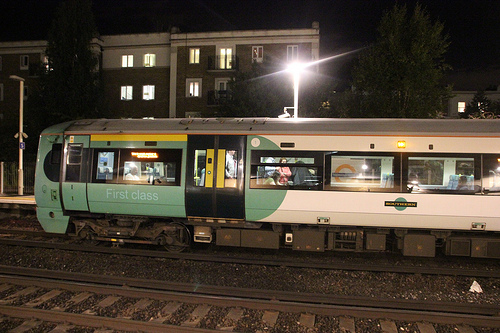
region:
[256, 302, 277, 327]
cross tie on the track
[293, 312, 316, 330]
cross tie on the track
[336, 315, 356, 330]
cross tie on the track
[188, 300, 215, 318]
cross tie on the track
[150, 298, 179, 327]
cross tie on the track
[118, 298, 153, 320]
cross tie on the track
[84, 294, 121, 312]
cross tie on the track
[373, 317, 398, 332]
cross tie on the track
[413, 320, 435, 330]
cross tie on the track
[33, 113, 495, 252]
the long train going down the track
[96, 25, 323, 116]
the building next to the trees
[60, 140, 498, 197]
the line of windows on the train compartment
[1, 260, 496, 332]
the empty track next to the train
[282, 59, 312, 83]
a very bright street light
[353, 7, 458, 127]
the many green leaves on the tree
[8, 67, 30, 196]
another street light that is not turned on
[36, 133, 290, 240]
the green section of the paint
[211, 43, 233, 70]
the double doors next to the balcony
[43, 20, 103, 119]
another leafy tree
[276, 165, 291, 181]
Woman wearing a pink sweater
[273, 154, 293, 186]
Woman standing on a train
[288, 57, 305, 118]
Light above a train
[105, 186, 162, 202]
First class written on the side of a train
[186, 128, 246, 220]
Closed doors on a train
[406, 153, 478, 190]
Window on the side of a train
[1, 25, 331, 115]
Building behind a train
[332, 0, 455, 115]
Green on a tree behind a train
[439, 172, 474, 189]
Blue seats on a train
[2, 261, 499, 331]
Metal train tracks in the gravel